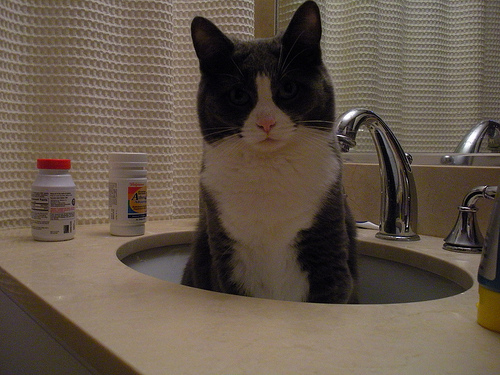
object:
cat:
[181, 0, 362, 305]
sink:
[116, 229, 474, 305]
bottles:
[30, 158, 78, 242]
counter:
[0, 216, 500, 375]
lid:
[36, 158, 71, 170]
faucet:
[334, 108, 421, 242]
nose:
[256, 113, 277, 133]